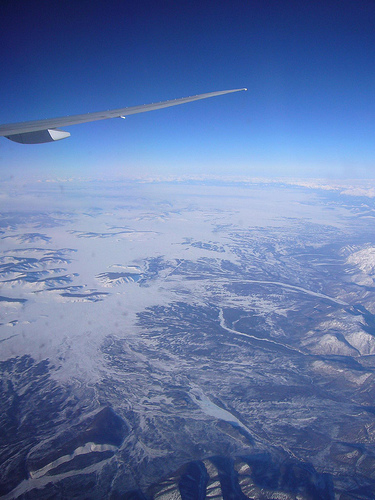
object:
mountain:
[302, 327, 359, 356]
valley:
[221, 458, 239, 499]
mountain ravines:
[179, 461, 212, 499]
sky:
[0, 16, 375, 177]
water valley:
[185, 388, 257, 439]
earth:
[0, 175, 375, 500]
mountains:
[347, 247, 374, 272]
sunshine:
[2, 237, 109, 324]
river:
[242, 279, 350, 307]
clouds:
[267, 163, 344, 176]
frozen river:
[216, 306, 303, 353]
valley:
[330, 451, 375, 500]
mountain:
[344, 328, 374, 358]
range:
[0, 165, 374, 497]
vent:
[5, 128, 71, 144]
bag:
[284, 169, 299, 184]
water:
[283, 377, 346, 479]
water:
[211, 294, 272, 361]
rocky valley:
[105, 410, 127, 452]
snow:
[0, 186, 375, 463]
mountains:
[59, 292, 108, 301]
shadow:
[333, 441, 368, 452]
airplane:
[0, 88, 248, 144]